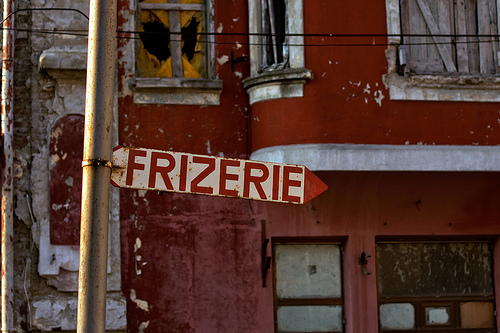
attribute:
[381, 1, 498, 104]
window frame — crumbling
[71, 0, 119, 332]
pole — gray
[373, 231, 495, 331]
window — glass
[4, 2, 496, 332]
building — run down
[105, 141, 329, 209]
sign — pointing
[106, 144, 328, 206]
black shirt — directional, red, white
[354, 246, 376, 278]
light fixture — broken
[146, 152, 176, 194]
letter — red 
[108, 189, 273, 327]
paint — peeling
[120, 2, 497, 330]
concrete wall — grey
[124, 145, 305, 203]
letters — red